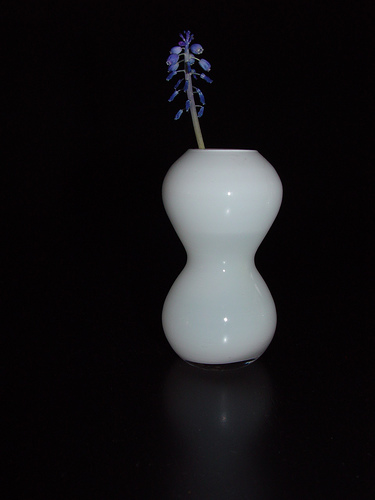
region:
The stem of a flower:
[193, 121, 197, 130]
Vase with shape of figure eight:
[184, 197, 255, 312]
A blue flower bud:
[168, 57, 176, 61]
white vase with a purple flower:
[121, 8, 356, 373]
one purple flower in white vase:
[160, 26, 224, 159]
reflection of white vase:
[143, 356, 281, 493]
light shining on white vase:
[209, 178, 241, 349]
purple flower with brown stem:
[161, 25, 224, 152]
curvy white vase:
[147, 136, 280, 368]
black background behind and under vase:
[13, 13, 336, 481]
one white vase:
[132, 140, 307, 379]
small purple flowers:
[169, 108, 183, 121]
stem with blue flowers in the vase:
[154, 27, 220, 141]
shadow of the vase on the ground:
[163, 360, 274, 471]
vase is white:
[155, 146, 279, 361]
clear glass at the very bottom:
[182, 356, 258, 371]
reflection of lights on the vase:
[219, 184, 236, 349]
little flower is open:
[186, 40, 207, 55]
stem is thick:
[187, 119, 206, 147]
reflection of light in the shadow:
[216, 386, 227, 429]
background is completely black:
[20, 90, 111, 239]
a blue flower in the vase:
[168, 29, 211, 148]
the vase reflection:
[167, 361, 266, 486]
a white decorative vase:
[160, 150, 284, 371]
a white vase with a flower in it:
[160, 31, 282, 369]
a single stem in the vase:
[187, 98, 204, 149]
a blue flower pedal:
[174, 108, 182, 120]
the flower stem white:
[183, 48, 203, 148]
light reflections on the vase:
[220, 189, 231, 343]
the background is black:
[2, 2, 370, 498]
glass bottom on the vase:
[185, 357, 254, 370]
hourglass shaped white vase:
[158, 148, 284, 366]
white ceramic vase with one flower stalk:
[163, 32, 283, 364]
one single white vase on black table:
[5, 27, 371, 496]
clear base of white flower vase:
[183, 358, 259, 367]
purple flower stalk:
[160, 28, 210, 148]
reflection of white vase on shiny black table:
[157, 353, 269, 496]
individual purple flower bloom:
[189, 42, 201, 53]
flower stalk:
[163, 30, 209, 148]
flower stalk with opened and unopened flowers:
[166, 30, 213, 149]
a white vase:
[141, 142, 293, 388]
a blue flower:
[165, 29, 211, 147]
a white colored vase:
[158, 148, 284, 370]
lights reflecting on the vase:
[221, 189, 229, 346]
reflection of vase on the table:
[163, 355, 271, 497]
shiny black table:
[2, 1, 373, 498]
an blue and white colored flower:
[189, 44, 205, 54]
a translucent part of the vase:
[159, 232, 277, 368]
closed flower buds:
[175, 27, 194, 46]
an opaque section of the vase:
[160, 148, 282, 232]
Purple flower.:
[161, 25, 222, 142]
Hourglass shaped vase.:
[153, 138, 283, 378]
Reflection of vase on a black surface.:
[166, 359, 299, 498]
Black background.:
[54, 330, 99, 405]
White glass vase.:
[152, 137, 288, 378]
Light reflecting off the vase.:
[218, 311, 231, 345]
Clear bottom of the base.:
[182, 354, 257, 372]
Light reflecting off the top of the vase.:
[221, 187, 235, 217]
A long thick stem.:
[177, 67, 212, 148]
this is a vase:
[109, 52, 279, 388]